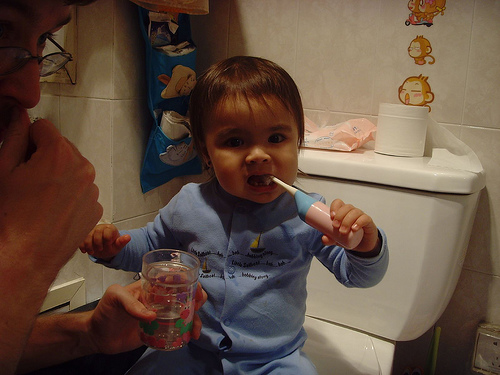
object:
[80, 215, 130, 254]
hand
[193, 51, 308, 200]
head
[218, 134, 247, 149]
eye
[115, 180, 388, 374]
shirt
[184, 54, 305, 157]
hair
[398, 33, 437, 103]
monkey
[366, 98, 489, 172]
paper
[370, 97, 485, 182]
roll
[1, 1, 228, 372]
person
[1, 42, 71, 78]
glasses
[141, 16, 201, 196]
organizer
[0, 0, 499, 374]
wall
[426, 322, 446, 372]
handle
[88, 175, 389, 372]
clothes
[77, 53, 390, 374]
baby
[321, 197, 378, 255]
hand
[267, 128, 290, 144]
eye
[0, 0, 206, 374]
man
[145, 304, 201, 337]
water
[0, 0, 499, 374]
toilet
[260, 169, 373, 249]
toothbrush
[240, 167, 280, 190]
baby mouth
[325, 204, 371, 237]
finger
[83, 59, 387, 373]
person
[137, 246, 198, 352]
glass